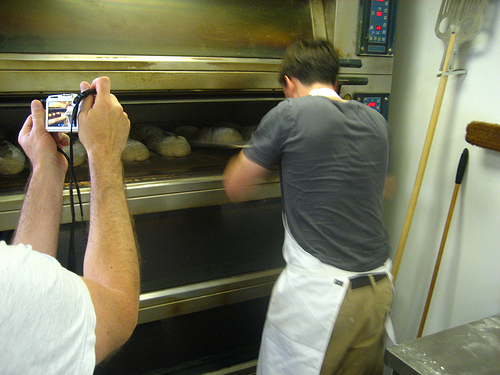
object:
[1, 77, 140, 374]
man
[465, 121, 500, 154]
push broom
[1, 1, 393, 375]
oven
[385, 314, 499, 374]
baking flour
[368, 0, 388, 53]
digital display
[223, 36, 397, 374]
bakers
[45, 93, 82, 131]
camera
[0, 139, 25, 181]
baking bread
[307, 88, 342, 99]
neck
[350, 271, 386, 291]
and a brown belt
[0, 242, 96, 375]
white t shirt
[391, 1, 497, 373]
baking tools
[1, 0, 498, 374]
bakery has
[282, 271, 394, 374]
khakis and a belt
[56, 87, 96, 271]
black strap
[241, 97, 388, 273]
grey t shirt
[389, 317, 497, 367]
counter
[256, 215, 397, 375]
apron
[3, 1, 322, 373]
stove